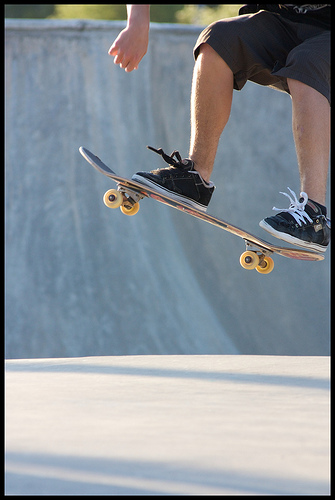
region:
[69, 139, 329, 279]
skateboard with yellow wheels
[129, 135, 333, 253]
black and white tennis shoes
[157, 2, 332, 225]
boy wearing black shorts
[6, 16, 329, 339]
grey concrete barrier behind boy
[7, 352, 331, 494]
white ground under skater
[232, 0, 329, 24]
edge of black and white t-shirt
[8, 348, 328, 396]
shadow of skateboarder on the ground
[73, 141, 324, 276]
black skateboard with red accents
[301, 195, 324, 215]
red and white tag on shoe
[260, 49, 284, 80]
rip in leg of black shorts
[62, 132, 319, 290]
Skating boar in the air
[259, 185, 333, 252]
Pair of black snickers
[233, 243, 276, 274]
Yellow rolling wheels of a skating board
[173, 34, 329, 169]
Uncovered legs of person skating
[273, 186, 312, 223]
White laces of snickers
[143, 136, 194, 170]
Black laces of snickers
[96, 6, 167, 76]
Wrist of the person skating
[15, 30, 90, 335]
Sloping wall of the skating arena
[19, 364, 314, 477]
Flat portion of the skating arena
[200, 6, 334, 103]
Pair of black shorts worn by the person skating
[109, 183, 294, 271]
four wheels on the skateboard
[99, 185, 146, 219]
wheels are yellow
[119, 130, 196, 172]
shoe lace is black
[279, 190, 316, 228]
shoe lace is white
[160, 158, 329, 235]
tennis shoes are black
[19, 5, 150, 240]
skateboard ramp wall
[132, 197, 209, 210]
white along the bottom of shoes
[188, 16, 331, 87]
man is wearing black shorts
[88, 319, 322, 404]
shadows on the cement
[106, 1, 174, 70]
skateboard's hand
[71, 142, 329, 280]
black skateboard with white wheels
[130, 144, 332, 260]
pair of black skate shoes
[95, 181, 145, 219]
plain white skateboard wheels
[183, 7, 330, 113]
plain black skate shorts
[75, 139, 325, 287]
black skateboard with logo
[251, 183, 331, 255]
black shoe with white laces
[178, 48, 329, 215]
pair of hairy legs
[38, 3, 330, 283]
person doing skateboard trick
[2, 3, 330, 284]
person riding a skateboard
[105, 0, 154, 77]
right hand pointing downward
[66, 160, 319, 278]
a skateboard with yellow wheels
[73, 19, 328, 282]
a person riding a skateboard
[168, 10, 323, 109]
a person wearing black shorts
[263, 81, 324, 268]
a black tennis shoe with a white lace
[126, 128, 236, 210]
a black tennis shoe with a black lace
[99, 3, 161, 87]
a persons hand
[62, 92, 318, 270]
a person on a skateboard off the ground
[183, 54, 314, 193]
a persons bare legs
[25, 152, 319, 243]
a skateboard in the air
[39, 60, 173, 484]
a concrete skateboard park